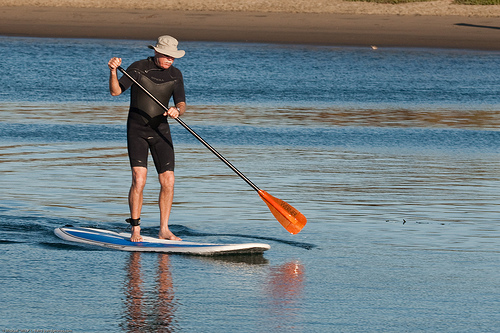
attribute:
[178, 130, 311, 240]
paddle — orange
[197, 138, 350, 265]
paddle — orange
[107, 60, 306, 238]
paddle — orange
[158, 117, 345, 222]
paddle — orange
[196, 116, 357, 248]
paddle — orange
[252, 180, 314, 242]
paddle — orange